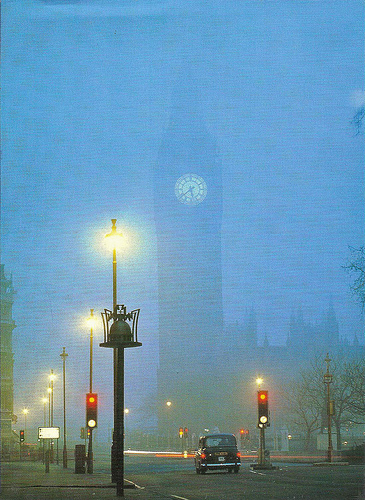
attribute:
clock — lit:
[173, 170, 215, 212]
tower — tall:
[151, 53, 234, 331]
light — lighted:
[99, 233, 132, 250]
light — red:
[84, 395, 98, 406]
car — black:
[190, 436, 242, 473]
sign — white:
[35, 426, 67, 447]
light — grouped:
[257, 391, 268, 403]